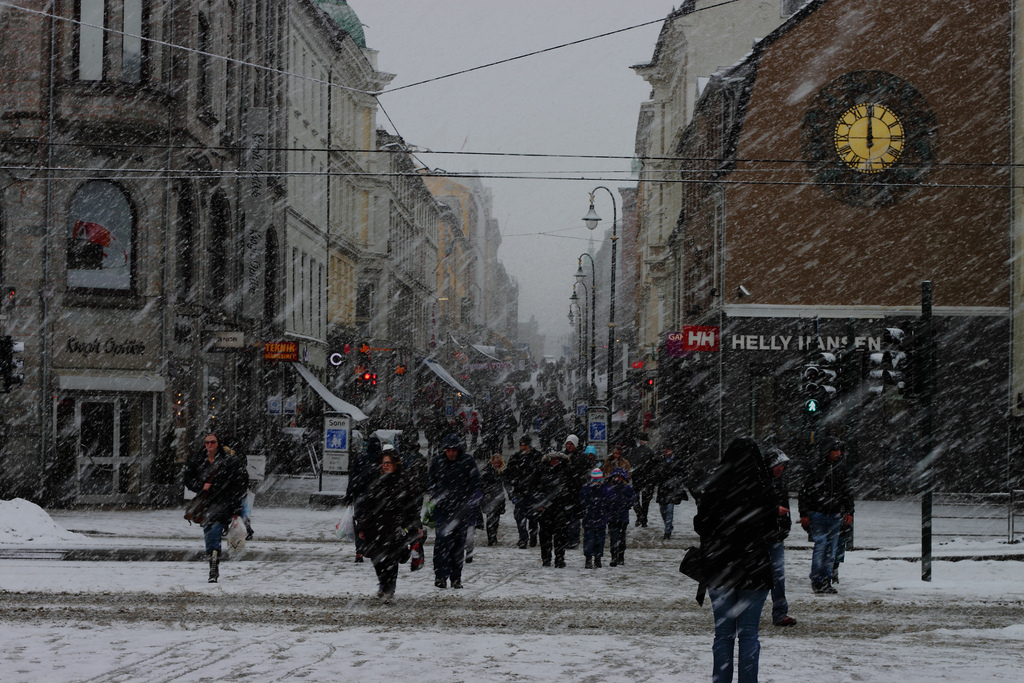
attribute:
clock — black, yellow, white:
[810, 69, 939, 212]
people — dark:
[178, 367, 877, 674]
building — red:
[7, 10, 1023, 551]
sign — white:
[720, 310, 886, 380]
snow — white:
[8, 479, 1021, 667]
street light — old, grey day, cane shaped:
[569, 181, 632, 484]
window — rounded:
[70, 150, 240, 340]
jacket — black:
[704, 471, 784, 597]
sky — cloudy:
[356, 3, 667, 373]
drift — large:
[4, 495, 1009, 597]